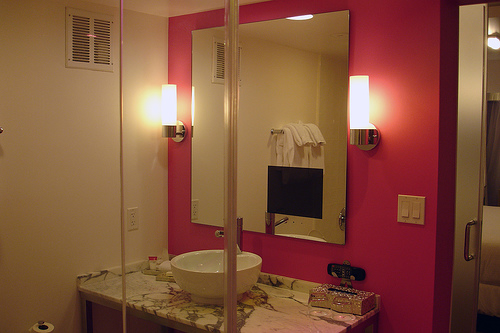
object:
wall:
[167, 2, 459, 333]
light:
[160, 84, 187, 143]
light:
[348, 74, 381, 152]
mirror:
[190, 9, 350, 245]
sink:
[170, 247, 263, 306]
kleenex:
[310, 281, 375, 316]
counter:
[76, 255, 381, 332]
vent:
[64, 6, 118, 74]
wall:
[1, 1, 168, 332]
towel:
[275, 127, 295, 167]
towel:
[305, 122, 327, 168]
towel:
[282, 122, 315, 168]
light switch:
[397, 193, 426, 225]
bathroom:
[1, 1, 500, 331]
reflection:
[269, 120, 329, 175]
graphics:
[127, 276, 283, 332]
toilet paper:
[29, 320, 53, 333]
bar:
[270, 127, 285, 136]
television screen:
[266, 164, 323, 219]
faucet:
[215, 217, 243, 254]